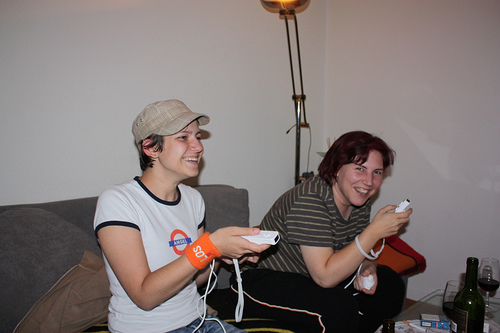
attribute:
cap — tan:
[127, 97, 212, 146]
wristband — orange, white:
[184, 231, 220, 272]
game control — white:
[234, 224, 283, 252]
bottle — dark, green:
[452, 253, 487, 333]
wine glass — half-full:
[477, 256, 499, 322]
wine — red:
[479, 276, 499, 290]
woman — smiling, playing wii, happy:
[88, 98, 270, 332]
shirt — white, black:
[91, 177, 213, 333]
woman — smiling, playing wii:
[232, 130, 414, 332]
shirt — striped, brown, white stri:
[249, 174, 372, 276]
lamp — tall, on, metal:
[260, 0, 313, 187]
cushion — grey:
[3, 208, 106, 333]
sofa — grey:
[0, 183, 249, 333]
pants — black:
[227, 265, 409, 333]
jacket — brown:
[10, 248, 111, 332]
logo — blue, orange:
[168, 228, 194, 256]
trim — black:
[129, 176, 181, 207]